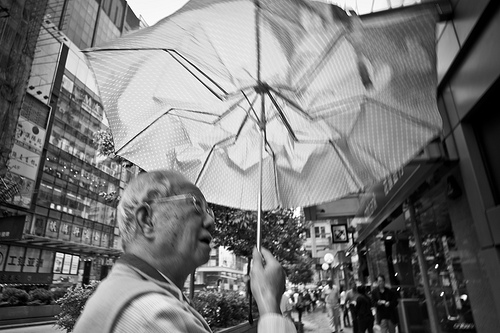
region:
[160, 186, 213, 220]
eye glasses on a man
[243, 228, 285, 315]
hand holding an umbrella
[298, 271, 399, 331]
people on the street corner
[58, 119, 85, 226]
windows on a building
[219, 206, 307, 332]
tree on the street corner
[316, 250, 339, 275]
circular lights on a street lamp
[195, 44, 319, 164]
browken bottom of an umbrella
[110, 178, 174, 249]
balding head on a man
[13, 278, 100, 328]
bushes on the side of the street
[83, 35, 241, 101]
wire on an umbrella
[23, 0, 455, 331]
old man holding an umbrella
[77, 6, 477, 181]
open and broken umbrella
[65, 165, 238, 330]
old man with glasses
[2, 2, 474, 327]
black and white photo of a man holding umbrella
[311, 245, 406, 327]
small group of people walking down the street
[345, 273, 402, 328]
people walking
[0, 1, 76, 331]
tall building with signs on it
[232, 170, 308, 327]
hand holding an umbrella handle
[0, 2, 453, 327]
man with glasses holding a broken umbrella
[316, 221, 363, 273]
shop signs on a busy street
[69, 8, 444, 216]
black and white broken umbrella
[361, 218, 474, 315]
reflections on a store front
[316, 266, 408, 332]
people walking by stores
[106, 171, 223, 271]
balding old man head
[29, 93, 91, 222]
shiny windows on a building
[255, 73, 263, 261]
metal support of an umbrella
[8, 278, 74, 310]
bushes by a building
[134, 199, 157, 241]
ear on an old man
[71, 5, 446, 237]
umbrella in man's hand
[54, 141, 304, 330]
man holding umbrella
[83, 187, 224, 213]
glasses on the man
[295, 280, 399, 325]
people walking on the sidewalk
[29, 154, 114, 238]
windows to a building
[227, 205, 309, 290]
trees along the sidewalk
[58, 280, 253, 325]
shrubs on the sidewalk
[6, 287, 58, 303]
shrubs on opposite side of street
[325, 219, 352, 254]
banner hanging off building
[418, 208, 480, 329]
window front of store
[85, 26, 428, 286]
A man holding the umbrella.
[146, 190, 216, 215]
The man is wearing glasses.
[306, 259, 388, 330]
People walking on the sidewalk.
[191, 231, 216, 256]
The man mouth is open.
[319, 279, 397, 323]
People standing in front of the store.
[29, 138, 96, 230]
Windows on the building.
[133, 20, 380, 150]
The umbrella is broken.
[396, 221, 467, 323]
The window on the store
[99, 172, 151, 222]
The man has grey hair.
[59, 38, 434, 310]
The photo is black and white.